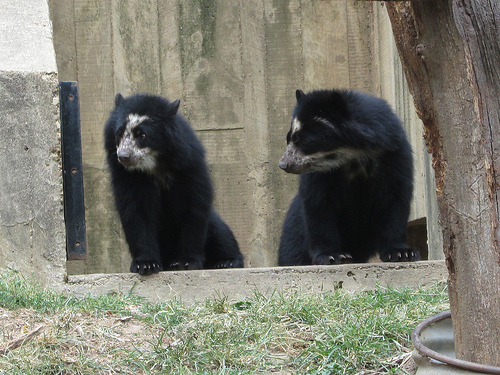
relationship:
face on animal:
[113, 108, 163, 176] [104, 92, 245, 276]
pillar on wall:
[45, 66, 86, 262] [5, 77, 64, 237]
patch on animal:
[109, 107, 158, 168] [104, 92, 245, 276]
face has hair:
[114, 109, 164, 171] [114, 108, 159, 176]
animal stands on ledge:
[276, 84, 420, 265] [69, 252, 446, 274]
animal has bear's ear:
[104, 92, 245, 276] [169, 99, 180, 115]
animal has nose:
[104, 92, 245, 276] [116, 148, 144, 170]